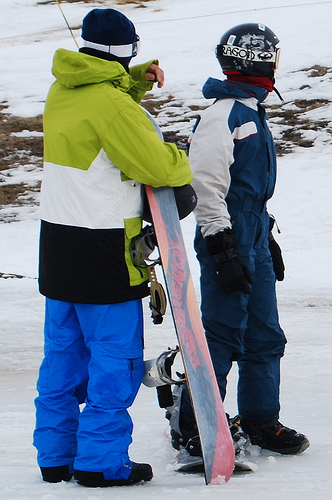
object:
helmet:
[214, 23, 282, 103]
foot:
[238, 416, 309, 456]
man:
[170, 20, 309, 456]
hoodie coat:
[35, 47, 193, 307]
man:
[31, 6, 192, 488]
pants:
[177, 199, 286, 436]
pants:
[32, 295, 143, 481]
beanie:
[77, 9, 141, 67]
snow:
[0, 0, 331, 499]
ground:
[0, 0, 331, 499]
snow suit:
[177, 74, 288, 443]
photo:
[0, 0, 331, 500]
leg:
[236, 248, 286, 432]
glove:
[204, 229, 256, 302]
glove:
[268, 215, 284, 281]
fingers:
[149, 65, 162, 85]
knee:
[256, 323, 286, 359]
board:
[139, 107, 237, 486]